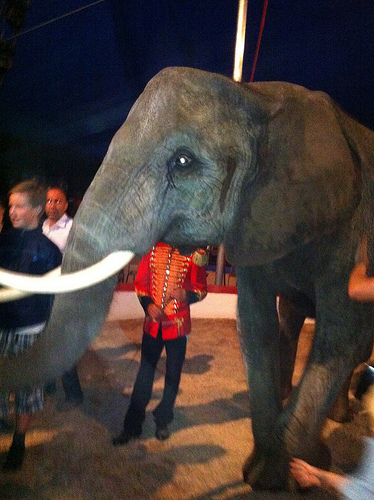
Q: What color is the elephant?
A: Gray.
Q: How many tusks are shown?
A: Two.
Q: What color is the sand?
A: Brown.